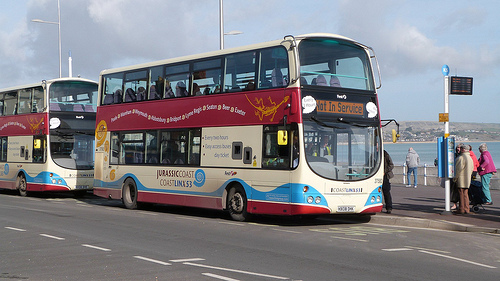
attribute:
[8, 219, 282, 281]
lines — white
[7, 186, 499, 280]
street — grey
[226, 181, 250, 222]
wheel — black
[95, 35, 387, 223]
bus — large, double decker, red, white, blue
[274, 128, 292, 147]
mirror — yellow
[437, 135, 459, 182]
sign — blue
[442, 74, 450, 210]
pole — white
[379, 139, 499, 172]
water — blue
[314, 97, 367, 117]
sign — lcd screen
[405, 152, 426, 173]
hoodie — gray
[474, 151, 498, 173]
jacket — pink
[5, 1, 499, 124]
sky — blue, white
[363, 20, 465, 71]
clouds — whtie, puffy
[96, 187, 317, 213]
stripe — red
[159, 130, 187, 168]
window — glass